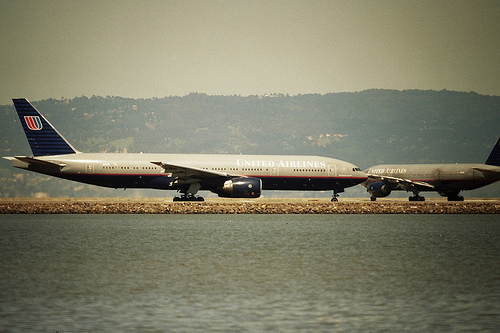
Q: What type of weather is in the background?
A: It is overcast.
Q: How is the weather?
A: It is overcast.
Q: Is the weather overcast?
A: Yes, it is overcast.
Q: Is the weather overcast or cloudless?
A: It is overcast.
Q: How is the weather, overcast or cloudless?
A: It is overcast.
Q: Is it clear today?
A: No, it is overcast.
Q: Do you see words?
A: Yes, there are words.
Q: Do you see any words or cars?
A: Yes, there are words.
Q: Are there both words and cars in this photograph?
A: No, there are words but no cars.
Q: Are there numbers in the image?
A: No, there are no numbers.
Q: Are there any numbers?
A: No, there are no numbers.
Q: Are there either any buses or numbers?
A: No, there are no numbers or buses.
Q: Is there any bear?
A: No, there are no bears.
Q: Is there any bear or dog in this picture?
A: No, there are no bears or dogs.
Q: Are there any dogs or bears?
A: No, there are no bears or dogs.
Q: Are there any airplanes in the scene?
A: Yes, there is an airplane.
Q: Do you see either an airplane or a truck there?
A: Yes, there is an airplane.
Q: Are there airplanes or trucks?
A: Yes, there is an airplane.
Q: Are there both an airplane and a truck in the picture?
A: No, there is an airplane but no trucks.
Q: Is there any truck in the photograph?
A: No, there are no trucks.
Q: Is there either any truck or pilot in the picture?
A: No, there are no trucks or pilots.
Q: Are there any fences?
A: No, there are no fences.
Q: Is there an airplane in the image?
A: Yes, there are airplanes.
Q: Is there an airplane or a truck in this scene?
A: Yes, there are airplanes.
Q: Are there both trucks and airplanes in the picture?
A: No, there are airplanes but no trucks.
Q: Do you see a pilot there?
A: No, there are no pilots.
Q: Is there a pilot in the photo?
A: No, there are no pilots.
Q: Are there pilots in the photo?
A: No, there are no pilots.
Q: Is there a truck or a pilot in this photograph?
A: No, there are no pilots or trucks.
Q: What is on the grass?
A: The airplanes are on the grass.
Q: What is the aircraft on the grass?
A: The aircraft is airplanes.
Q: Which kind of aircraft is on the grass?
A: The aircraft is airplanes.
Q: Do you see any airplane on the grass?
A: Yes, there are airplanes on the grass.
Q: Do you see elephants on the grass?
A: No, there are airplanes on the grass.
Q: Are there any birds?
A: No, there are no birds.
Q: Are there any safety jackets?
A: No, there are no safety jackets.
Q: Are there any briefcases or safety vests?
A: No, there are no safety vests or briefcases.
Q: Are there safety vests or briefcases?
A: No, there are no safety vests or briefcases.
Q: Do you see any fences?
A: No, there are no fences.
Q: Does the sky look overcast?
A: Yes, the sky is overcast.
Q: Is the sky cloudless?
A: No, the sky is overcast.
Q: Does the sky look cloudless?
A: No, the sky is overcast.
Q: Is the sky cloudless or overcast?
A: The sky is overcast.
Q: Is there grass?
A: Yes, there is grass.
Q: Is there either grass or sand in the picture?
A: Yes, there is grass.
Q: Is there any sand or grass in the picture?
A: Yes, there is grass.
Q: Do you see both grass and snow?
A: No, there is grass but no snow.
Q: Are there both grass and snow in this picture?
A: No, there is grass but no snow.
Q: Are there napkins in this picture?
A: No, there are no napkins.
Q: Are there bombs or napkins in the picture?
A: No, there are no napkins or bombs.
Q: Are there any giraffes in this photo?
A: No, there are no giraffes.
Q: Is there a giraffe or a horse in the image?
A: No, there are no giraffes or horses.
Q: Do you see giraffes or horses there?
A: No, there are no giraffes or horses.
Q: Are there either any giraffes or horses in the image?
A: No, there are no giraffes or horses.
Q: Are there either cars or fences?
A: No, there are no fences or cars.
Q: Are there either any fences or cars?
A: No, there are no fences or cars.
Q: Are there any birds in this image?
A: No, there are no birds.